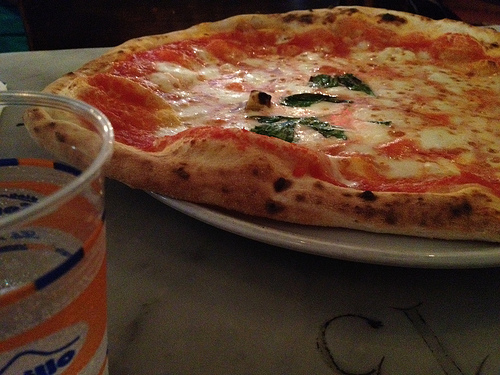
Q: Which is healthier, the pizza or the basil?
A: The basil is healthier than the pizza.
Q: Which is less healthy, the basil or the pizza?
A: The pizza is less healthy than the basil.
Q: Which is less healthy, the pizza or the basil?
A: The pizza is less healthy than the basil.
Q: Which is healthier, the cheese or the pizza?
A: The cheese is healthier than the pizza.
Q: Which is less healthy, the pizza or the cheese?
A: The pizza is less healthy than the cheese.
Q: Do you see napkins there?
A: No, there are no napkins.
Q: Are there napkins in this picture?
A: No, there are no napkins.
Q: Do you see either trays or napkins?
A: No, there are no napkins or trays.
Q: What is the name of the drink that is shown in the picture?
A: The drink is soda.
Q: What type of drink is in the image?
A: The drink is soda.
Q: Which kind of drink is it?
A: The drink is soda.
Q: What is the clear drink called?
A: The drink is soda.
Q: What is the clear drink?
A: The drink is soda.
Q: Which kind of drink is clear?
A: The drink is soda.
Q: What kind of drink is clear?
A: The drink is soda.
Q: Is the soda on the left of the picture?
A: Yes, the soda is on the left of the image.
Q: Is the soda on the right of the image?
A: No, the soda is on the left of the image.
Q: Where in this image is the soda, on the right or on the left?
A: The soda is on the left of the image.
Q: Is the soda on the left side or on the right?
A: The soda is on the left of the image.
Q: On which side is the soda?
A: The soda is on the left of the image.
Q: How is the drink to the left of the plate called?
A: The drink is soda.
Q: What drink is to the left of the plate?
A: The drink is soda.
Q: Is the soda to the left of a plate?
A: Yes, the soda is to the left of a plate.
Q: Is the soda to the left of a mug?
A: No, the soda is to the left of a plate.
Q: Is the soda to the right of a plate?
A: No, the soda is to the left of a plate.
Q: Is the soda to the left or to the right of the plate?
A: The soda is to the left of the plate.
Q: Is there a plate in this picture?
A: Yes, there is a plate.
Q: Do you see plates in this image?
A: Yes, there is a plate.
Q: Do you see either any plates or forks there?
A: Yes, there is a plate.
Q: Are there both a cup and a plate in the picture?
A: Yes, there are both a plate and a cup.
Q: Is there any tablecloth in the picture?
A: No, there are no tablecloths.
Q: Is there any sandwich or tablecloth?
A: No, there are no tablecloths or sandwiches.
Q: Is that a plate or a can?
A: That is a plate.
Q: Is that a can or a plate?
A: That is a plate.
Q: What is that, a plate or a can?
A: That is a plate.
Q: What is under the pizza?
A: The plate is under the pizza.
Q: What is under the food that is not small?
A: The plate is under the pizza.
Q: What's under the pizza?
A: The plate is under the pizza.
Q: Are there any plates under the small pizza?
A: Yes, there is a plate under the pizza.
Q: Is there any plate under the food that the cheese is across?
A: Yes, there is a plate under the pizza.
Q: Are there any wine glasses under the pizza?
A: No, there is a plate under the pizza.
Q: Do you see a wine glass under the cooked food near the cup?
A: No, there is a plate under the pizza.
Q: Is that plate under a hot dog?
A: No, the plate is under the pizza.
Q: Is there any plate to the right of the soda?
A: Yes, there is a plate to the right of the soda.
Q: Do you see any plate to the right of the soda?
A: Yes, there is a plate to the right of the soda.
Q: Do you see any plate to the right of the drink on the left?
A: Yes, there is a plate to the right of the soda.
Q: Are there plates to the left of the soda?
A: No, the plate is to the right of the soda.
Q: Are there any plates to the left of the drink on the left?
A: No, the plate is to the right of the soda.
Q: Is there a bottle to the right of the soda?
A: No, there is a plate to the right of the soda.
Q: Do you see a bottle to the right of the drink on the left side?
A: No, there is a plate to the right of the soda.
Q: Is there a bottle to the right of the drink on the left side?
A: No, there is a plate to the right of the soda.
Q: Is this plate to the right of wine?
A: No, the plate is to the right of the soda.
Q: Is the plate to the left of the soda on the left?
A: No, the plate is to the right of the soda.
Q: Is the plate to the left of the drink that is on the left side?
A: No, the plate is to the right of the soda.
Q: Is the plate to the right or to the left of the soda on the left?
A: The plate is to the right of the soda.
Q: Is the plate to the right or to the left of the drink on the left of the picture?
A: The plate is to the right of the soda.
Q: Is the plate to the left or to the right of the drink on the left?
A: The plate is to the right of the soda.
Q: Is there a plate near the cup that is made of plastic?
A: Yes, there is a plate near the cup.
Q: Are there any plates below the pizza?
A: Yes, there is a plate below the pizza.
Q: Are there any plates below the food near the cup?
A: Yes, there is a plate below the pizza.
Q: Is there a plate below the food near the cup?
A: Yes, there is a plate below the pizza.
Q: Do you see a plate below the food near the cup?
A: Yes, there is a plate below the pizza.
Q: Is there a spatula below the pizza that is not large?
A: No, there is a plate below the pizza.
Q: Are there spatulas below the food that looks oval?
A: No, there is a plate below the pizza.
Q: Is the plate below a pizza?
A: Yes, the plate is below a pizza.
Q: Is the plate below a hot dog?
A: No, the plate is below a pizza.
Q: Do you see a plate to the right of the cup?
A: Yes, there is a plate to the right of the cup.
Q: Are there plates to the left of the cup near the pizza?
A: No, the plate is to the right of the cup.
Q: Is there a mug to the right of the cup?
A: No, there is a plate to the right of the cup.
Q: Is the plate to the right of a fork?
A: No, the plate is to the right of a cup.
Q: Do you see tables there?
A: Yes, there is a table.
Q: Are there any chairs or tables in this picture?
A: Yes, there is a table.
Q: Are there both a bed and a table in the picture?
A: No, there is a table but no beds.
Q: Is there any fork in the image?
A: No, there are no forks.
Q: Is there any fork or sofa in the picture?
A: No, there are no forks or sofas.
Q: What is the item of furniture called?
A: The piece of furniture is a table.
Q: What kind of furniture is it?
A: The piece of furniture is a table.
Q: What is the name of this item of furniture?
A: This is a table.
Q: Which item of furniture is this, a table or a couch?
A: This is a table.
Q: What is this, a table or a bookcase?
A: This is a table.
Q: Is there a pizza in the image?
A: Yes, there is a pizza.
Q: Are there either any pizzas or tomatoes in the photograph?
A: Yes, there is a pizza.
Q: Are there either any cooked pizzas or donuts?
A: Yes, there is a cooked pizza.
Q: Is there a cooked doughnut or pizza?
A: Yes, there is a cooked pizza.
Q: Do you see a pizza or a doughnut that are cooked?
A: Yes, the pizza is cooked.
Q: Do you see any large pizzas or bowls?
A: Yes, there is a large pizza.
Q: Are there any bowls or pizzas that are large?
A: Yes, the pizza is large.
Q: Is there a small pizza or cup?
A: Yes, there is a small pizza.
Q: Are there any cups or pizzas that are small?
A: Yes, the pizza is small.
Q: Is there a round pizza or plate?
A: Yes, there is a round pizza.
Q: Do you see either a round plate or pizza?
A: Yes, there is a round pizza.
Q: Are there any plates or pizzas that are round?
A: Yes, the pizza is round.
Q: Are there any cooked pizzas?
A: Yes, there is a cooked pizza.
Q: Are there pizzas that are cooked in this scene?
A: Yes, there is a cooked pizza.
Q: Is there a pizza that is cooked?
A: Yes, there is a pizza that is cooked.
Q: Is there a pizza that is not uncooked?
A: Yes, there is an cooked pizza.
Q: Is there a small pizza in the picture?
A: Yes, there is a small pizza.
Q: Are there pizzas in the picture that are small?
A: Yes, there is a pizza that is small.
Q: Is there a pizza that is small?
A: Yes, there is a pizza that is small.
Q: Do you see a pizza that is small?
A: Yes, there is a pizza that is small.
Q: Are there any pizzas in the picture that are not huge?
A: Yes, there is a small pizza.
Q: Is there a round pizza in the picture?
A: Yes, there is a round pizza.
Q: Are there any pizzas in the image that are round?
A: Yes, there is a pizza that is round.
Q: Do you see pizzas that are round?
A: Yes, there is a pizza that is round.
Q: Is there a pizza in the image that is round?
A: Yes, there is a pizza that is round.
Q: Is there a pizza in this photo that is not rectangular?
A: Yes, there is a round pizza.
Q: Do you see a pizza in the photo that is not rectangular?
A: Yes, there is a round pizza.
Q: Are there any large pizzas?
A: Yes, there is a large pizza.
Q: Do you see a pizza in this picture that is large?
A: Yes, there is a pizza that is large.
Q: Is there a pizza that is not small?
A: Yes, there is a large pizza.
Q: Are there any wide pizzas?
A: Yes, there is a wide pizza.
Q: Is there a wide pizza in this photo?
A: Yes, there is a wide pizza.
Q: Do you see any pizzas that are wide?
A: Yes, there is a pizza that is wide.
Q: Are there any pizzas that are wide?
A: Yes, there is a pizza that is wide.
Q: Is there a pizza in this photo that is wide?
A: Yes, there is a pizza that is wide.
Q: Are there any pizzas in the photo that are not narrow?
A: Yes, there is a wide pizza.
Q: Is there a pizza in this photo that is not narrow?
A: Yes, there is a wide pizza.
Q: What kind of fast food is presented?
A: The fast food is a pizza.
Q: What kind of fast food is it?
A: The food is a pizza.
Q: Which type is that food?
A: This is a pizza.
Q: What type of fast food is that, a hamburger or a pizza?
A: This is a pizza.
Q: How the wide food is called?
A: The food is a pizza.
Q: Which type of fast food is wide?
A: The fast food is a pizza.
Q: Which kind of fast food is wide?
A: The fast food is a pizza.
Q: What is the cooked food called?
A: The food is a pizza.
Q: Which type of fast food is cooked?
A: The fast food is a pizza.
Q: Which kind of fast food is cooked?
A: The fast food is a pizza.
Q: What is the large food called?
A: The food is a pizza.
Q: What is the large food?
A: The food is a pizza.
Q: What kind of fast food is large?
A: The fast food is a pizza.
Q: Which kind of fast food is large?
A: The fast food is a pizza.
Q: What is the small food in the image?
A: The food is a pizza.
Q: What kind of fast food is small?
A: The fast food is a pizza.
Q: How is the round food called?
A: The food is a pizza.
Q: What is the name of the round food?
A: The food is a pizza.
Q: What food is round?
A: The food is a pizza.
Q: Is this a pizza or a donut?
A: This is a pizza.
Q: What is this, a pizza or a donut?
A: This is a pizza.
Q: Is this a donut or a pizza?
A: This is a pizza.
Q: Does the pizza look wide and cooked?
A: Yes, the pizza is wide and cooked.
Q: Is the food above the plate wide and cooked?
A: Yes, the pizza is wide and cooked.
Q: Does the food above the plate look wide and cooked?
A: Yes, the pizza is wide and cooked.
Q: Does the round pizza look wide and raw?
A: No, the pizza is wide but cooked.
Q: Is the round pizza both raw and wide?
A: No, the pizza is wide but cooked.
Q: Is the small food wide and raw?
A: No, the pizza is wide but cooked.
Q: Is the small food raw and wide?
A: No, the pizza is wide but cooked.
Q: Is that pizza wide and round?
A: Yes, the pizza is wide and round.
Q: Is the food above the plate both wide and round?
A: Yes, the pizza is wide and round.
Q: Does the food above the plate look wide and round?
A: Yes, the pizza is wide and round.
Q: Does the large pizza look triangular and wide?
A: No, the pizza is wide but round.